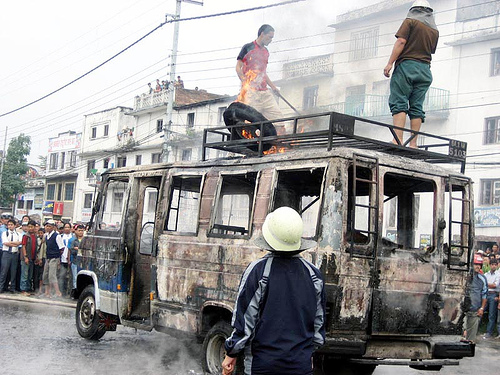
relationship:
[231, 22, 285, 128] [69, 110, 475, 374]
man standing on car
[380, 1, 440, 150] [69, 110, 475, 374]
man standing on car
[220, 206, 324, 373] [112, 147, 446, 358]
man standing in truck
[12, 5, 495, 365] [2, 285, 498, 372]
smoke covering street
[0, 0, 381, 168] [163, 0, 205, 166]
sky behind pole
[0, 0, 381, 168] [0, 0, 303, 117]
sky behind wire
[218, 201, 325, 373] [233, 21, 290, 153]
man standing in front of others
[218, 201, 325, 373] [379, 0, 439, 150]
man standing in front of others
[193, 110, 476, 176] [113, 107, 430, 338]
platform on top of truck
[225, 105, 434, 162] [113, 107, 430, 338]
railing on top of truck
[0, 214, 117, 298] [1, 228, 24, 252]
person wearing a shirt and tie shirt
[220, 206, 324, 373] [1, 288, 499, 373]
man standing on pavement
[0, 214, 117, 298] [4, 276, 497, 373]
person standing on pavement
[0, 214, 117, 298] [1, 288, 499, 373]
person standing on pavement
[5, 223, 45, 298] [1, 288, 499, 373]
person standing on pavement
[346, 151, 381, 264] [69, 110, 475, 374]
ladder on car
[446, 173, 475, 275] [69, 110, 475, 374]
ladder on car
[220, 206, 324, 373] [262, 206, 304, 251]
man wearing hard hat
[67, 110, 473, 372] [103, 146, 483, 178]
car has roof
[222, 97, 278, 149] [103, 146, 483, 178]
tire on roof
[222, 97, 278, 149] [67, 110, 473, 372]
tire on car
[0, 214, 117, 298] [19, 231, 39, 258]
person wearing vest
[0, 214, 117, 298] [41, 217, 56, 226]
person wearing hat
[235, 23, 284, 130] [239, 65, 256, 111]
man starting fire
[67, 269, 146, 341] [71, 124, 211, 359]
tire in front of bus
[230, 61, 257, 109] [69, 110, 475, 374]
flame on top of car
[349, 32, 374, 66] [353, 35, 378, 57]
window has bars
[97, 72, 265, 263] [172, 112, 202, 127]
building has window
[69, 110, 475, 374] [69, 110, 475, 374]
car has car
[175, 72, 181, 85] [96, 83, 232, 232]
people on top of building